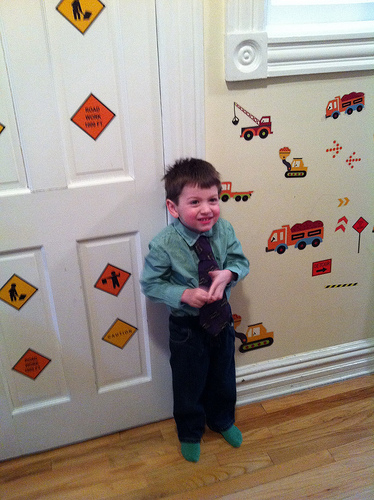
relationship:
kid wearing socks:
[140, 158, 250, 463] [180, 428, 241, 461]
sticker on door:
[69, 93, 116, 140] [3, 3, 174, 457]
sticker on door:
[102, 318, 138, 350] [3, 3, 174, 457]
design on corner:
[234, 41, 260, 70] [222, 30, 269, 87]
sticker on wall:
[265, 218, 323, 253] [205, 4, 370, 372]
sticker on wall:
[229, 102, 274, 140] [205, 4, 370, 372]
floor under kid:
[2, 373, 374, 496] [140, 158, 250, 463]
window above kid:
[267, 4, 373, 36] [140, 158, 250, 463]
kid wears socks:
[140, 158, 250, 463] [180, 428, 241, 461]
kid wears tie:
[140, 158, 250, 463] [194, 238, 235, 331]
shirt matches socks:
[141, 221, 249, 314] [180, 428, 241, 461]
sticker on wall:
[281, 144, 309, 178] [205, 4, 370, 372]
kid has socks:
[140, 158, 250, 463] [180, 428, 241, 461]